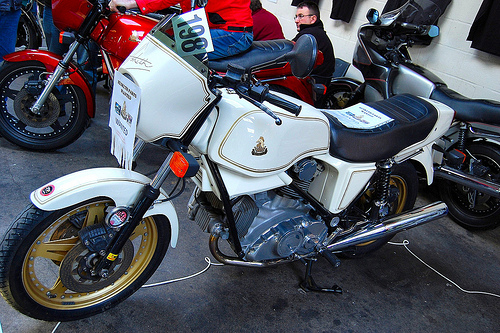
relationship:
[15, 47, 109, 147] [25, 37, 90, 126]
wheel under a fender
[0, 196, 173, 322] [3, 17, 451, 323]
black tire part of bike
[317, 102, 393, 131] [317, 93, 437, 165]
note attached to seat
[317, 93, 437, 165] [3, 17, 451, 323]
seat part of bike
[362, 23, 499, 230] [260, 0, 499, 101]
bike against wall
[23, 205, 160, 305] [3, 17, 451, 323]
gold rim part of bike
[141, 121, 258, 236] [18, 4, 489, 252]
bars part of bike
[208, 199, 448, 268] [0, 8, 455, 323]
exhaust pipe part of motorbike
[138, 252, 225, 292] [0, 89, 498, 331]
cord laying on ground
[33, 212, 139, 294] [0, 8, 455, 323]
black tire part of motorbike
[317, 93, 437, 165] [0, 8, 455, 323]
seat part of motorbike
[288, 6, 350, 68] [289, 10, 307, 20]
man wearing glasses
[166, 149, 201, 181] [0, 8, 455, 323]
signal part of motorbike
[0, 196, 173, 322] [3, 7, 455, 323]
black tire part of bike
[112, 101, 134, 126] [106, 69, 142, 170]
graphic printed on sign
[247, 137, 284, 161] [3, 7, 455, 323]
logo printed on bike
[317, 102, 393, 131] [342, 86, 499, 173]
note attached to seat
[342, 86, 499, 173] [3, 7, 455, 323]
seat part of bike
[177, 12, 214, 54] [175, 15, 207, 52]
number printed on 198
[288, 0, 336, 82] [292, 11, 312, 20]
man wearing glasses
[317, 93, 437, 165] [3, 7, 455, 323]
seat part of bike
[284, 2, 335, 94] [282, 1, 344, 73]
glasses on man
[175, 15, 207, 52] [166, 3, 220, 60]
198 on label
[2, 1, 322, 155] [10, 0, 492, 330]
motorcycle in parking lot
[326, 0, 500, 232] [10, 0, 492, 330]
bike in parking lot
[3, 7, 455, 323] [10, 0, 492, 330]
bike in parking lot